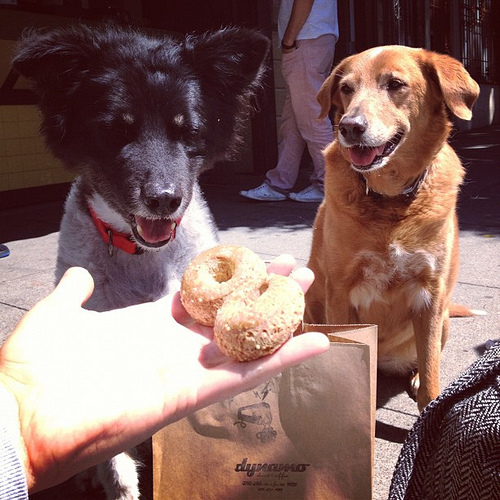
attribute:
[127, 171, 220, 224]
nose — black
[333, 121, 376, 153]
nose — black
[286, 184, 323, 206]
shoe — white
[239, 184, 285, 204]
shoe — white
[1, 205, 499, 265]
shadow line — behind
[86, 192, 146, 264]
collar — red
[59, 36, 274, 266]
dog — black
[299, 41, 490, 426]
dog — brown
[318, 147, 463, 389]
fur — white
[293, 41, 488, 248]
dog — sitting, light colored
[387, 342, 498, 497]
fabric — black, white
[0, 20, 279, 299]
dog — sitting, dark colored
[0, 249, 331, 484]
hand — in a pocket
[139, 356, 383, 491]
brown bag — dynamo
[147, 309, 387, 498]
brown bag — dynamo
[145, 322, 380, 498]
bag — paper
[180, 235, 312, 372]
doughnuts — tan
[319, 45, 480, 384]
dog — brown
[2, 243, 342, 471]
hand — outstretched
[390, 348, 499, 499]
hat? — black, gray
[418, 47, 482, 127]
ear — down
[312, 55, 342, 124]
ear — down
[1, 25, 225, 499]
dog — black, gray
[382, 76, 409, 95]
eye — black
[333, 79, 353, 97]
eye — black